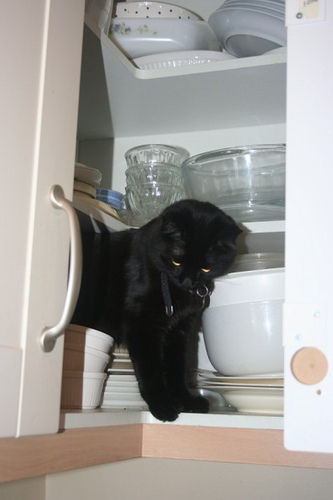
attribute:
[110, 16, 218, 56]
baking pan — white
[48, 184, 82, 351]
handle — SILVER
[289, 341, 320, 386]
hinge — white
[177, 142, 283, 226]
bowl — LARGE, PLASTIC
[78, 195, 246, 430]
cat — BLACK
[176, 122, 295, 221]
bowl — large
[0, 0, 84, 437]
door — small, white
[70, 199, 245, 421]
black cat — small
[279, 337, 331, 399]
circle — SMALL, LIGHT BROWN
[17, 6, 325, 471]
cabinet — white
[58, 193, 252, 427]
cat — BLACK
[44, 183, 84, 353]
cabinet handle — SILVER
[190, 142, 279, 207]
bowl — BIG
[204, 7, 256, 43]
bowls — WHITE, SMALL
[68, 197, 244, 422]
cat — SMALL, BLACK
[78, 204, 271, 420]
cat — BLACK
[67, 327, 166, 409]
dishes — WHITE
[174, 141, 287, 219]
bowl — glass